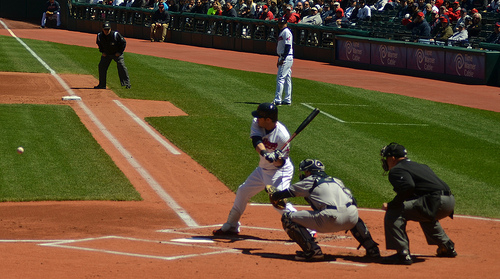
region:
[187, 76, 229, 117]
the turf is green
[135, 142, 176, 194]
the turf is brown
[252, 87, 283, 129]
the helmet is black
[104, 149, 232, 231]
the line is white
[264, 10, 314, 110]
the man is standing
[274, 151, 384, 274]
the catching is crouching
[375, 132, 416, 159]
the hat is black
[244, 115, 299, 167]
the shirt is white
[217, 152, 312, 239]
the pants are white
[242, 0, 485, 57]
there's a large crowd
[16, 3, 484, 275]
Picture of a baseball game.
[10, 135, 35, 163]
White baseball in the air.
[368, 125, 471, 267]
Home plate umpire.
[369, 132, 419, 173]
Protective face gear on umpire.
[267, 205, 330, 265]
Protective shin guard on catcher.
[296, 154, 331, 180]
Protective head gear on catcher.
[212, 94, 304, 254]
Batter getting ready to swing at ball.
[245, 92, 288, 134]
Black safety helmet on batter.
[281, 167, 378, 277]
Grey baseball uniform.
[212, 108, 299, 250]
White baseball uniform.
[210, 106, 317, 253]
Green grass on the ball field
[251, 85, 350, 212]
The batter ready to hit the ball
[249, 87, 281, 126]
A helmet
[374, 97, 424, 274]
Umpire watching the play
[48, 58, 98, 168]
First base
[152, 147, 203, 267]
White line on the field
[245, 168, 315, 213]
The glove on the catcher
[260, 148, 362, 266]
The catcher has a mask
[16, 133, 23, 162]
Ball in the air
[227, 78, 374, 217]
Batter ready to swing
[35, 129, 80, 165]
the turf is green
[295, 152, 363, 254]
the pitcher is crouching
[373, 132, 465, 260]
the umpire is crouching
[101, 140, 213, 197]
the line is white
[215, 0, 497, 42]
the crowd is large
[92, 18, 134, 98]
Umpire/Referee on the 1st base.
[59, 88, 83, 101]
First base square on the field.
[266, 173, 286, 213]
Glove in the catcher's hand.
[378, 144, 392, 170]
Face guard worn by the umpire behind the catcher.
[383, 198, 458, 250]
Gray pants worn by the umpire behind the catcher.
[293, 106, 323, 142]
Black tip of the bat.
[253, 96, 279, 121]
Black helmet on the batter's head.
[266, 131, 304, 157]
Wooden part of the baseball bat.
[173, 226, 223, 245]
Home base plate in front of the batter.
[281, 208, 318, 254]
Knee guard on the catcher's knee.